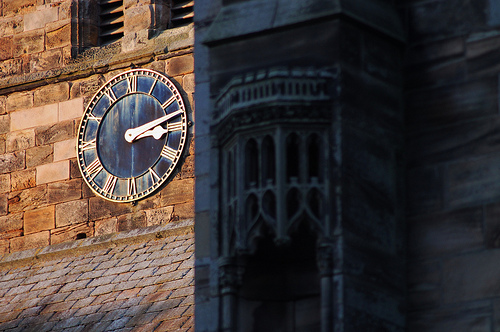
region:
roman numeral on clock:
[123, 73, 140, 93]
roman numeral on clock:
[146, 75, 158, 93]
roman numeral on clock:
[159, 93, 175, 110]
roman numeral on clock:
[166, 120, 183, 135]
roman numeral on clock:
[158, 142, 175, 162]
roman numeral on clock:
[146, 166, 160, 185]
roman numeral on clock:
[126, 177, 139, 197]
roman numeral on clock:
[101, 174, 118, 197]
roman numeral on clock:
[83, 155, 101, 179]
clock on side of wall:
[74, 63, 176, 185]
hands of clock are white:
[126, 106, 186, 143]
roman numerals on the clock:
[74, 69, 196, 202]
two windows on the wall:
[63, 3, 191, 42]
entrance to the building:
[213, 253, 353, 324]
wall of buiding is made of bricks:
[7, 73, 73, 260]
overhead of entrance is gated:
[209, 68, 339, 250]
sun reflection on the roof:
[2, 275, 158, 325]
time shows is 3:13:
[95, 104, 190, 142]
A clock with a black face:
[74, 66, 190, 205]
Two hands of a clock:
[121, 105, 190, 142]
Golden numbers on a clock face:
[81, 75, 183, 195]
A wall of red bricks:
[11, 128, 73, 215]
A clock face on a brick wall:
[76, 67, 191, 204]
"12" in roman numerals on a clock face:
[123, 73, 138, 97]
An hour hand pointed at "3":
[125, 124, 170, 140]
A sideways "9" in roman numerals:
[79, 137, 97, 152]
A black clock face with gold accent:
[76, 66, 186, 201]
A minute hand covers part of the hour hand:
[125, 107, 184, 142]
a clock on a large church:
[4, 58, 194, 208]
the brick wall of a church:
[12, 129, 74, 237]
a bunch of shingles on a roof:
[31, 259, 141, 330]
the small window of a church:
[180, 85, 322, 252]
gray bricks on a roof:
[392, 96, 489, 246]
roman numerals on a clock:
[82, 71, 139, 102]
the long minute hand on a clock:
[125, 109, 187, 127]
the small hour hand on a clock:
[130, 126, 172, 147]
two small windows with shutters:
[50, 8, 160, 52]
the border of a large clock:
[107, 179, 144, 213]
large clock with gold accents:
[57, 58, 197, 210]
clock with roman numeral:
[69, 53, 183, 201]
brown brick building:
[10, 5, 187, 239]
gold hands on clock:
[117, 103, 187, 150]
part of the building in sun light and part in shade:
[8, 28, 440, 318]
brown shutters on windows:
[57, 1, 201, 54]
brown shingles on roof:
[7, 220, 204, 330]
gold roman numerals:
[68, 58, 188, 208]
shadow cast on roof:
[12, 280, 192, 327]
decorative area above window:
[211, 65, 349, 268]